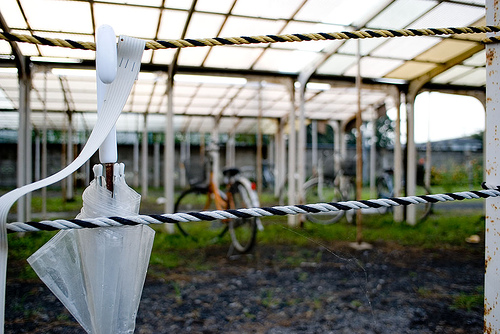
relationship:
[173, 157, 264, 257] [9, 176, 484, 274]
bicycle on grass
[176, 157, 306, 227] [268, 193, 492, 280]
bicycle on grass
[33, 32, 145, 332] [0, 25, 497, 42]
umbrella on rope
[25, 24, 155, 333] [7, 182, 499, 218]
umbrella on rope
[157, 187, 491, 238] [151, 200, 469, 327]
grass on ground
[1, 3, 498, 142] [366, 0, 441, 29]
roof has white panel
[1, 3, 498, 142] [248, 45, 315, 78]
roof has white panel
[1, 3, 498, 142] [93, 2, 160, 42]
roof has white panel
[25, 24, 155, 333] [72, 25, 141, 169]
umbrella has handle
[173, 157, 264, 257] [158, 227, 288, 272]
bicycle on grass